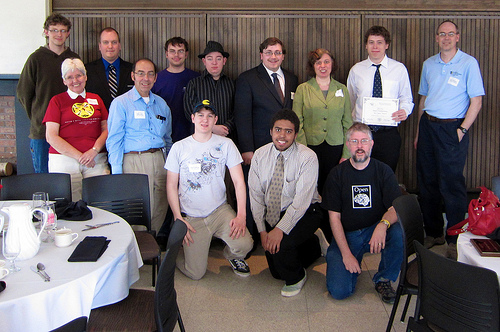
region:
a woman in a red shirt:
[41, 55, 108, 178]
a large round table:
[0, 188, 132, 328]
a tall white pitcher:
[2, 203, 51, 254]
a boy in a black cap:
[168, 98, 255, 280]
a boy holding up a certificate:
[348, 30, 407, 170]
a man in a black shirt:
[326, 125, 406, 305]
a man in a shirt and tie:
[251, 118, 319, 293]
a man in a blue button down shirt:
[108, 56, 175, 236]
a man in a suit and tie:
[237, 40, 297, 168]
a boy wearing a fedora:
[181, 35, 236, 138]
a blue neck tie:
[372, 63, 385, 99]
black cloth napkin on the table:
[68, 229, 110, 264]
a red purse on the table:
[449, 190, 497, 237]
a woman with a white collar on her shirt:
[47, 58, 106, 153]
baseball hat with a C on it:
[188, 100, 218, 119]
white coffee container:
[0, 200, 47, 262]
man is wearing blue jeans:
[326, 220, 402, 291]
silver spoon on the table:
[33, 258, 52, 284]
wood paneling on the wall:
[53, 8, 499, 130]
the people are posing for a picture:
[24, 15, 476, 253]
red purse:
[467, 183, 499, 228]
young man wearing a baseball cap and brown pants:
[168, 99, 248, 283]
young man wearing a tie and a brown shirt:
[243, 113, 317, 298]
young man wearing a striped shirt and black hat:
[197, 40, 229, 105]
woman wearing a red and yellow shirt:
[38, 58, 108, 185]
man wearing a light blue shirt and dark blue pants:
[418, 19, 483, 231]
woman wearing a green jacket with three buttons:
[298, 46, 342, 157]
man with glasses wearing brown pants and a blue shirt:
[116, 58, 164, 170]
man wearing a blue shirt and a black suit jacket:
[88, 24, 125, 91]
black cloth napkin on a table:
[58, 197, 91, 221]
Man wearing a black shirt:
[324, 126, 409, 307]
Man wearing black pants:
[244, 114, 327, 296]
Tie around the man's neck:
[262, 147, 287, 228]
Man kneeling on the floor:
[160, 101, 262, 280]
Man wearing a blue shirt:
[104, 54, 174, 229]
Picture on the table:
[3, 199, 45, 261]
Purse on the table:
[442, 174, 498, 239]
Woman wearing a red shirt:
[42, 54, 107, 176]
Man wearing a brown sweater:
[17, 9, 90, 174]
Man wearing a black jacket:
[77, 21, 134, 98]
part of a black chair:
[409, 251, 499, 330]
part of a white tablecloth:
[0, 195, 147, 329]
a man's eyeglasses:
[133, 67, 159, 79]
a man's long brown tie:
[262, 149, 287, 227]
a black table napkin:
[67, 236, 109, 263]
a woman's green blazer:
[292, 73, 359, 157]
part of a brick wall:
[2, 99, 19, 160]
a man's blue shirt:
[417, 51, 484, 121]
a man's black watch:
[456, 125, 472, 135]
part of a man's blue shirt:
[150, 70, 182, 105]